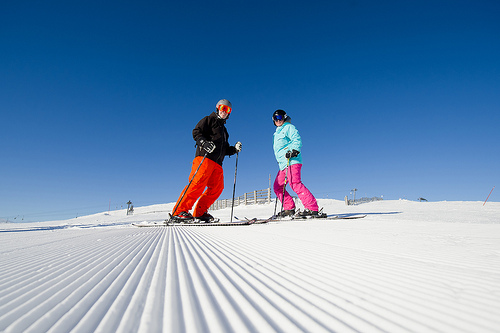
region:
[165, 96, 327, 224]
Two skiers standing on skis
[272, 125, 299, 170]
woman wearing an aqua colored ski jacket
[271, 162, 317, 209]
Pink ski pants worn by the woman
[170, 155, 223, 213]
Man wearing red ski pants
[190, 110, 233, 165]
Black jacket worn by the man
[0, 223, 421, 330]
Groves in the white snow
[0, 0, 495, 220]
Beautiful blue sky above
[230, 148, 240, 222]
Left ski stick of the man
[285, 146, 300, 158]
Black gloves worn by the woman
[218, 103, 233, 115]
Man wearing red ski goggles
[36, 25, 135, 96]
blue sky above the land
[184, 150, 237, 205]
orange pants on the person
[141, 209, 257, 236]
skis on the ground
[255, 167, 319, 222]
pink pants on person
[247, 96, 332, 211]
blue and pink outfit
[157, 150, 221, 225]
ski pole in hand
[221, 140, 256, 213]
ski pole in left hand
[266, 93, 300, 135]
helmet on the person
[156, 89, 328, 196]
two people looking towards the camera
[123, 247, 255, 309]
lines in the snow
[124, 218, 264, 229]
Nice skis on the white snow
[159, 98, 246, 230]
Man skiing in the winter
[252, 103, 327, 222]
Women skiing on the slopes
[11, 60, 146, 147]
Clear blue sky on a nice winter day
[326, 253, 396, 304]
Snow in the back drop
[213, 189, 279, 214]
Fence in the back round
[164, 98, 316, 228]
Couple skiing together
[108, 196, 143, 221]
Objects in the backround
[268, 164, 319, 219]
Warm Pink winter pants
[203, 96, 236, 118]
Man wearing protective helmet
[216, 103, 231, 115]
bright orange goggles over a skier's eyes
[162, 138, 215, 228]
black ski pole in a skier's hand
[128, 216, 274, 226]
skis on a snowy ground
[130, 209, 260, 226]
ski equipment attached to a person's feet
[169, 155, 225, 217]
orange pants on a skier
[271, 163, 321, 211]
pink pants on a skier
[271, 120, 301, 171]
light blue coat on a woman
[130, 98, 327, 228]
two skiers on a snowy ground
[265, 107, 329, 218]
female skier wearing a blue coat and pink pants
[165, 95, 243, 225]
skier wearing black and orange clothing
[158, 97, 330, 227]
two people skiing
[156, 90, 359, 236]
a man and woman skiing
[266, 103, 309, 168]
a woman wearing a blue jacket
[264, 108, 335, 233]
a woman wearing pink pants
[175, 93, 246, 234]
a man wearing a black jacket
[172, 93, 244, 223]
a man wearing orange pants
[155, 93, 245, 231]
a man holding ski poles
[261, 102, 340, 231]
a woman holding ski poles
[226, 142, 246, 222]
a black and white ski pole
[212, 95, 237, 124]
a man wearing orange ski goggles